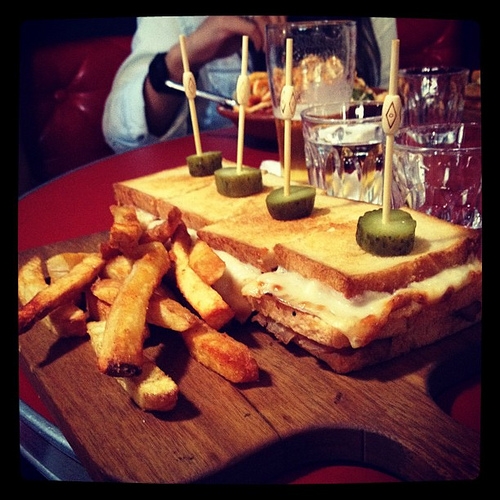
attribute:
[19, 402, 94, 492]
table edge — silver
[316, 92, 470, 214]
cups — glass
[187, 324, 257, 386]
fry — brown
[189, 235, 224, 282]
fry — brown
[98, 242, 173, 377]
fry — brown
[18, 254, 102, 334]
fry — brown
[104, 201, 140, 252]
fry — brown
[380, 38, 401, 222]
wood skewer — wood 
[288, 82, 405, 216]
glass — full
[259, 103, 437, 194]
toothpicks — four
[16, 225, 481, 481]
cutting board — cutting 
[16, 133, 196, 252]
table — red, round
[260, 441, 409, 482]
table — red, round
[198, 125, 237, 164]
table — round, red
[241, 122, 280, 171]
table — round, red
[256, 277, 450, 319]
cheese — melted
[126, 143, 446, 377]
cheese — melted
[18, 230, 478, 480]
platter — wood 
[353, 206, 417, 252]
pickle — skewered 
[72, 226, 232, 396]
fries — Pile , french 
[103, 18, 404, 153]
lady —  bowl 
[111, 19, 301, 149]
lady — bare arm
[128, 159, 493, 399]
sandwich — cut into fours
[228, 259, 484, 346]
cheese — melted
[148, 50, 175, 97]
item — black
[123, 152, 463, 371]
bread — toasted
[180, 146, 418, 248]
pickles — four, sliced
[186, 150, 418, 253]
pickles — four sliced   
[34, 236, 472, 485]
board — wood 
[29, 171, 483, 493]
tray — serving 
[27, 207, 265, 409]
fries —  French 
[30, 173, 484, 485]
platter —  serving 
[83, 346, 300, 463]
board — wood  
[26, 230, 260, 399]
fries — French   